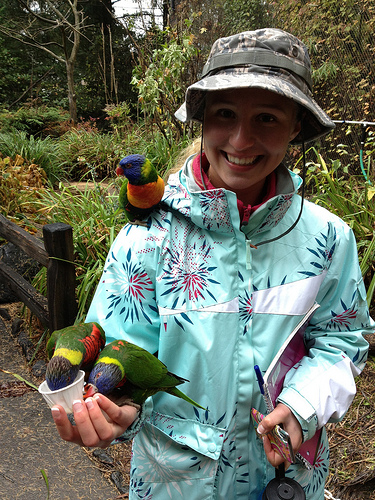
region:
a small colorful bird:
[113, 152, 164, 227]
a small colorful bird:
[80, 340, 210, 410]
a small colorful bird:
[44, 322, 106, 391]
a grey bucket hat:
[173, 27, 334, 145]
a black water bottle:
[259, 460, 304, 498]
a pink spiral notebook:
[261, 303, 322, 470]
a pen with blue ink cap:
[253, 364, 271, 413]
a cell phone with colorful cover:
[248, 406, 295, 467]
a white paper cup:
[38, 368, 84, 412]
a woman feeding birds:
[38, 27, 373, 498]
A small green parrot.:
[81, 340, 211, 411]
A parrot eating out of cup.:
[45, 319, 106, 391]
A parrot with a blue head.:
[113, 153, 164, 226]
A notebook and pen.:
[253, 300, 321, 414]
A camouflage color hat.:
[173, 26, 336, 145]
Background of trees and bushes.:
[0, 0, 373, 326]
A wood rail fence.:
[0, 212, 75, 330]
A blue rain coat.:
[83, 146, 374, 499]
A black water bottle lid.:
[261, 461, 306, 498]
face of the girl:
[173, 43, 315, 182]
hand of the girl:
[44, 383, 144, 453]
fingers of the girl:
[49, 405, 107, 428]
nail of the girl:
[254, 421, 271, 437]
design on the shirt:
[148, 452, 187, 484]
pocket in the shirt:
[138, 408, 247, 491]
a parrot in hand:
[55, 335, 177, 403]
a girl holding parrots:
[16, 333, 182, 472]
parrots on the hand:
[25, 302, 174, 461]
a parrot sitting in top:
[97, 146, 184, 220]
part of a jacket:
[302, 412, 304, 415]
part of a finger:
[118, 406, 124, 420]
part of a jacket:
[192, 413, 211, 444]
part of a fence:
[64, 318, 72, 335]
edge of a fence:
[43, 233, 76, 268]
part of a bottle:
[277, 461, 285, 476]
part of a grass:
[353, 449, 359, 457]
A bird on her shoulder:
[97, 140, 166, 231]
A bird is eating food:
[44, 308, 98, 389]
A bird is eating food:
[84, 343, 185, 416]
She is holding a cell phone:
[245, 387, 310, 485]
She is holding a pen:
[233, 333, 294, 420]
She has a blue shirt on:
[185, 312, 262, 367]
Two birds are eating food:
[33, 290, 201, 433]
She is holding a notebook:
[250, 320, 352, 475]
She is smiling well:
[172, 83, 318, 194]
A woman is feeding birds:
[30, 17, 370, 493]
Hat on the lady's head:
[165, 16, 338, 196]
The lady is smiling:
[190, 78, 305, 195]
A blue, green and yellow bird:
[92, 139, 174, 230]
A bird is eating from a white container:
[25, 307, 108, 420]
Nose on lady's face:
[221, 117, 256, 156]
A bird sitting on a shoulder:
[99, 139, 191, 260]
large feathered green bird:
[42, 322, 106, 390]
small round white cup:
[38, 367, 85, 436]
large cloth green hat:
[174, 28, 334, 145]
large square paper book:
[259, 303, 324, 470]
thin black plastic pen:
[253, 363, 265, 393]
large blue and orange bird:
[112, 154, 166, 223]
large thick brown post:
[43, 218, 76, 328]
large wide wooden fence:
[0, 212, 75, 331]